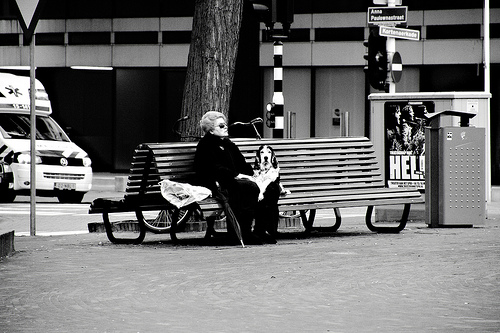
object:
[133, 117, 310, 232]
bicycle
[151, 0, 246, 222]
tree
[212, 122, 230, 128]
glasses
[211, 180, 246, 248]
umbrella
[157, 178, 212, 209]
bag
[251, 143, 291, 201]
dog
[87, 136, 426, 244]
bench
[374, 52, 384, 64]
light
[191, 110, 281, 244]
woman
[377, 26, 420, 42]
signs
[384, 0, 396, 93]
pole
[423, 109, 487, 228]
trash can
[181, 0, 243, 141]
trunk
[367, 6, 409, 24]
sign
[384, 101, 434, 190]
poster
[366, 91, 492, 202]
service box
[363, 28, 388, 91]
traffic signal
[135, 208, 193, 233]
wheel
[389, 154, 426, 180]
help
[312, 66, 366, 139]
window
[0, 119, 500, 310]
waiting area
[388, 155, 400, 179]
h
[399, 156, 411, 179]
e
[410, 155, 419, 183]
l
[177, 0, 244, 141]
bark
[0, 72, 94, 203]
truck